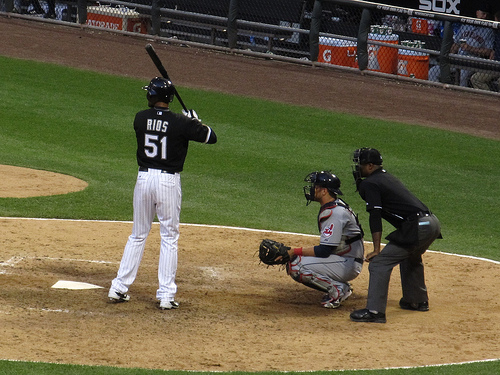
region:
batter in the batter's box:
[93, 36, 264, 286]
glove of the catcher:
[231, 228, 302, 302]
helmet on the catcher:
[285, 161, 335, 213]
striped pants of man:
[98, 170, 201, 261]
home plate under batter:
[41, 245, 112, 345]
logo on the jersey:
[310, 217, 342, 252]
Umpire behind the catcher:
[347, 133, 445, 275]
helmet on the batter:
[133, 73, 177, 114]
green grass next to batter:
[221, 113, 276, 186]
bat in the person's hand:
[136, 37, 170, 70]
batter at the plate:
[91, 55, 231, 212]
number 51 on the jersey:
[127, 125, 184, 180]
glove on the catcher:
[239, 223, 297, 293]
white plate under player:
[49, 263, 101, 312]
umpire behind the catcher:
[330, 117, 437, 229]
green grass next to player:
[243, 116, 307, 188]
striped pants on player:
[78, 188, 191, 287]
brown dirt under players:
[210, 314, 278, 359]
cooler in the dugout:
[306, 26, 366, 76]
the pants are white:
[121, 177, 203, 316]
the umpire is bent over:
[351, 164, 451, 331]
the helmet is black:
[305, 168, 341, 193]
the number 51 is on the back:
[134, 128, 182, 167]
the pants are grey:
[364, 260, 394, 312]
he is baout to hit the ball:
[106, 65, 223, 307]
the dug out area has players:
[280, 7, 497, 89]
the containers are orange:
[326, 33, 433, 85]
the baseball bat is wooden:
[141, 46, 178, 79]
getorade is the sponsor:
[312, 36, 357, 66]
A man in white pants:
[106, 134, 259, 356]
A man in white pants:
[142, 143, 209, 277]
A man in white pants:
[144, 187, 239, 342]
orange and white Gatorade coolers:
[312, 16, 427, 77]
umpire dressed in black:
[335, 136, 440, 326]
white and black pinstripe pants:
[108, 167, 180, 303]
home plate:
[50, 273, 106, 293]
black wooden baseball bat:
[138, 35, 195, 117]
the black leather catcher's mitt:
[255, 230, 295, 270]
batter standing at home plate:
[105, 30, 220, 311]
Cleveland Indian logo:
[312, 220, 342, 240]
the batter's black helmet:
[130, 70, 180, 108]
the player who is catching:
[253, 161, 383, 316]